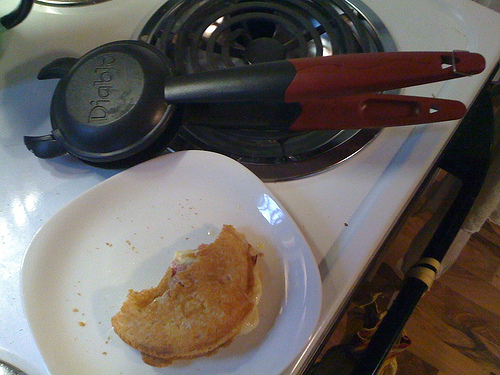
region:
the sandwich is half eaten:
[116, 215, 266, 361]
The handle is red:
[293, 50, 486, 145]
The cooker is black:
[42, 27, 280, 189]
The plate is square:
[14, 160, 329, 372]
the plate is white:
[50, 183, 295, 353]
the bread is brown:
[125, 249, 243, 350]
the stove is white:
[4, 5, 489, 312]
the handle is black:
[365, 205, 476, 372]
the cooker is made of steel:
[26, 58, 274, 160]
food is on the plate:
[117, 235, 266, 347]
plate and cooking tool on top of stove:
[8, 7, 483, 358]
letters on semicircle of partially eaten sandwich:
[107, 217, 267, 362]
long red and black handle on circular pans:
[20, 40, 485, 160]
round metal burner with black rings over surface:
[137, 6, 398, 177]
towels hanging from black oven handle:
[315, 75, 495, 371]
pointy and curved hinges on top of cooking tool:
[21, 45, 71, 160]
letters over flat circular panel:
[80, 47, 121, 122]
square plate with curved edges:
[20, 145, 325, 370]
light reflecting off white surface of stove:
[0, 170, 40, 335]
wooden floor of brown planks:
[335, 170, 496, 368]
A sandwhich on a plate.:
[112, 220, 268, 367]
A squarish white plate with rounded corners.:
[17, 147, 324, 374]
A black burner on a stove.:
[132, 0, 394, 182]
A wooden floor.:
[324, 170, 499, 373]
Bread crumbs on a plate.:
[101, 195, 201, 252]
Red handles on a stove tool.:
[284, 47, 485, 135]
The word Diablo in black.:
[82, 50, 117, 124]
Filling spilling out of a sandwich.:
[238, 268, 263, 335]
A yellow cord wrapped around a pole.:
[408, 255, 443, 295]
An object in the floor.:
[314, 290, 411, 374]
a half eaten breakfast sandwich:
[70, 266, 272, 350]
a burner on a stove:
[147, 2, 395, 169]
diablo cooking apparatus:
[28, 23, 480, 175]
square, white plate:
[1, 160, 324, 370]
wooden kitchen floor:
[440, 301, 483, 362]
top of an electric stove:
[4, 6, 390, 268]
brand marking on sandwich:
[157, 270, 209, 321]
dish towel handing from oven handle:
[372, 278, 419, 372]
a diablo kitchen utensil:
[24, 22, 481, 165]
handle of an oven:
[393, 80, 455, 359]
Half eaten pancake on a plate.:
[112, 225, 264, 365]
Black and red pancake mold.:
[23, 38, 486, 157]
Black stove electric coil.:
[137, 3, 412, 179]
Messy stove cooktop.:
[5, 7, 472, 374]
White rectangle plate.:
[16, 155, 322, 371]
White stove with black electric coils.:
[7, 2, 489, 358]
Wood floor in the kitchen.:
[418, 245, 498, 370]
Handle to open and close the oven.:
[400, 128, 489, 372]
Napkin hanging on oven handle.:
[425, 161, 498, 295]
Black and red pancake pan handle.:
[167, 43, 492, 128]